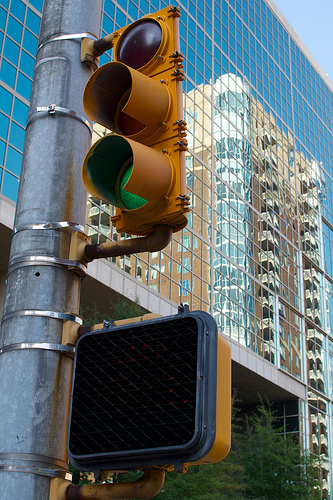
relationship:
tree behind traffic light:
[69, 293, 328, 498] [80, 5, 189, 233]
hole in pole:
[30, 268, 43, 279] [5, 3, 115, 497]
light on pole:
[86, 10, 184, 195] [2, 3, 104, 499]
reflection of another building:
[177, 65, 330, 495] [0, 0, 332, 499]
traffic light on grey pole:
[80, 3, 188, 261] [46, 6, 67, 216]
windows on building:
[194, 57, 330, 316] [0, 0, 332, 499]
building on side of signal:
[0, 0, 332, 499] [72, 11, 201, 254]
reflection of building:
[215, 92, 311, 173] [236, 14, 324, 100]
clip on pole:
[1, 308, 85, 323] [0, 1, 76, 499]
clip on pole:
[4, 255, 88, 274] [0, 1, 76, 499]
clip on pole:
[0, 464, 72, 480] [0, 1, 76, 499]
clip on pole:
[22, 105, 92, 136] [0, 1, 76, 499]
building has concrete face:
[70, 247, 315, 480] [82, 246, 329, 401]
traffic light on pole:
[80, 3, 188, 261] [2, 3, 104, 499]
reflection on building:
[177, 65, 330, 495] [187, 2, 332, 405]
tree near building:
[69, 293, 328, 498] [187, 2, 332, 405]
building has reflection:
[0, 0, 332, 499] [182, 65, 329, 379]